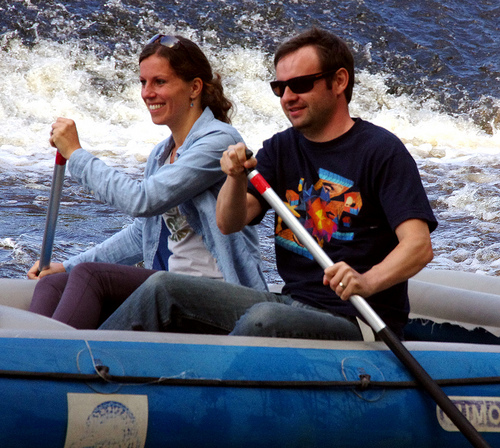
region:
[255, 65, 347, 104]
Sunglasses on man's face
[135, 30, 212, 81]
Glasses on woman's head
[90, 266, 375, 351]
Blue jeans man's wearing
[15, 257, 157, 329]
Purple pants woman's wearing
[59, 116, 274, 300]
Blue sweater woman's wearing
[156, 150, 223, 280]
White undershirt woman's wearing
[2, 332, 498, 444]
Blue side of raft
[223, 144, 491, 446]
Oar in man's hands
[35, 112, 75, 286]
Oar in woman's hands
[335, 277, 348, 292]
Ring on man's finger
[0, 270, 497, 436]
a blue and grey raft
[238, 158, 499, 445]
a silver black and red oar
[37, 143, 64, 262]
a silver and red oar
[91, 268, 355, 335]
a pair of men's jeans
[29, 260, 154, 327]
a pair of purple pants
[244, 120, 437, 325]
a black printed t-shirt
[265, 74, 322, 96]
a pair of black sunglasses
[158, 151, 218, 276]
a white printed t-shirt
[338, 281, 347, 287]
a man's wedding band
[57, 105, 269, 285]
a long sleeve blue shirt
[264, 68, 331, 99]
the glasses on the man's face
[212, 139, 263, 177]
the man's right hand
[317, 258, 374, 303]
the man's left hand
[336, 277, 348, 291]
the ring on the man's finger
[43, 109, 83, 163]
the woman's left hand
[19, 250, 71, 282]
the woman's right hand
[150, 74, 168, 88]
the woman's left eye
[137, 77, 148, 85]
the woman's right eye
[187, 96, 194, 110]
the earring hanging from the woman's ear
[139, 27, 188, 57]
the sunglasses on the woman's head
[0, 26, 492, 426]
A couple rowing in a small boat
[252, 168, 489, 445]
A grey and black oar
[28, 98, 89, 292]
A grey and red oar in the woman's hand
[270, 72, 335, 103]
Black sunglasses on the man's face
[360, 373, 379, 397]
A small black protrusion on the boat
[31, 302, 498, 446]
A small grey and blue boat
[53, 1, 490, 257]
The water looks quite rough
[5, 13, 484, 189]
A large wave behind the couple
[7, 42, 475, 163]
Splashing white sea foam near the boat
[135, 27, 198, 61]
Reflective sunglasses on the woman's head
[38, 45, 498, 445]
two people paddling a raft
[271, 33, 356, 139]
man wearing sunglasses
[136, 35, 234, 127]
woman wearing sunglasses on top of her head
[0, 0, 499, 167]
violent rapids flowing downstream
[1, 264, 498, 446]
blue raft in the water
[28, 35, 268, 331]
woman wearing purple pants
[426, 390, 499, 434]
logo on the side of the boat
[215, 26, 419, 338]
man wearing a graphic t-shirt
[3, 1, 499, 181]
water splashing down the river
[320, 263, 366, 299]
man wearing a ring on his left hand